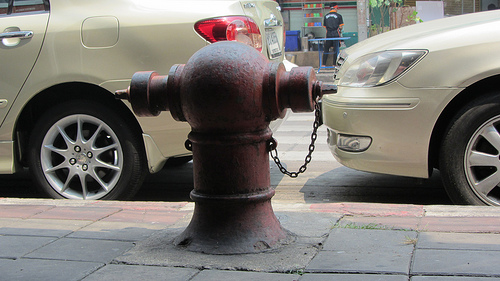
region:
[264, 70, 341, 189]
chain on a fire hydrant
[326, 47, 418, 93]
headlight on a car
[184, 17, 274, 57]
taillight on a car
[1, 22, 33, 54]
door handle on a car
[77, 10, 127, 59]
gas tank door on a car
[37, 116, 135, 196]
wheel of a tire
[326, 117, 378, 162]
parking light on a car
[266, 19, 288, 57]
license plate on a car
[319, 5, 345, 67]
man wearing a black shirt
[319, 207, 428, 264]
block in a sidewalk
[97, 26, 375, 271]
fire hydrant on a sidewalk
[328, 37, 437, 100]
front headlight on a vehicle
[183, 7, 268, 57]
rear tail light on a vehicle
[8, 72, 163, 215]
rear wheel on a vehicle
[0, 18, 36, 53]
door handle on a vehicle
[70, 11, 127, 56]
gas cap cover on a vehicle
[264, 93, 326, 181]
chain on a fire hydrant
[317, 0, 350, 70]
person standing on a sidewalk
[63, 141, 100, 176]
four lug nuts on a wheel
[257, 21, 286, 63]
rear licence plate on a vehicle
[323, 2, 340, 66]
a man stands around on the other side of the street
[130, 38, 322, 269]
a fire hydrant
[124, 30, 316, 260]
an old weather fire hydrant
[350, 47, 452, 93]
headlight of a car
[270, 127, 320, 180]
a length of chain attached to a fire hydrant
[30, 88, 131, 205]
rear wheel of a vehicle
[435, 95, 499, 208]
front wheel of a vehicle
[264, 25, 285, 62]
license plate of a car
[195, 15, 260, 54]
tail lights of a car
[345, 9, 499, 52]
hood of an automobile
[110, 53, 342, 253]
fire hydrant is red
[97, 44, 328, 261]
an old fire hydrant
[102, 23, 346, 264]
a weathered fire hydrant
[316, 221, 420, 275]
an individual paving stone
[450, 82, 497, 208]
wheel of car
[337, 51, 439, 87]
head of a car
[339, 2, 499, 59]
hood of a car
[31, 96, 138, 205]
rear wheel of a car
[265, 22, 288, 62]
license plate of car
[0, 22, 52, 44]
door latch of car